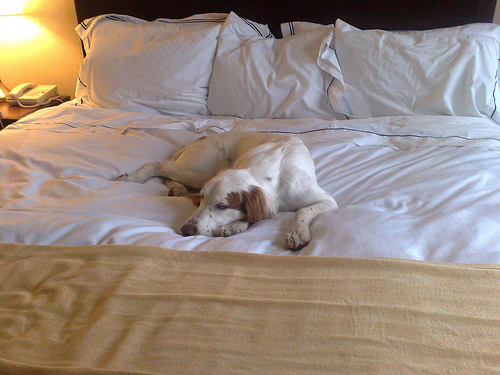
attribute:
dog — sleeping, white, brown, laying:
[110, 130, 338, 251]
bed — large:
[0, 0, 499, 373]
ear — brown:
[243, 186, 271, 224]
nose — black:
[181, 227, 198, 237]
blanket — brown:
[0, 242, 499, 374]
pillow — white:
[74, 13, 229, 117]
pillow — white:
[208, 9, 347, 122]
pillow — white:
[334, 17, 499, 120]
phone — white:
[6, 82, 65, 108]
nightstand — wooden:
[0, 95, 70, 132]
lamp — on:
[0, 81, 11, 102]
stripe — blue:
[492, 60, 499, 124]